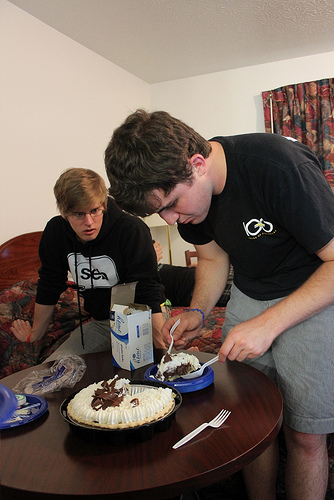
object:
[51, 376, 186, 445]
pie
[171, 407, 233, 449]
fork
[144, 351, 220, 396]
plates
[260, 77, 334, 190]
curtain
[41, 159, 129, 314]
boy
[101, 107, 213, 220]
hair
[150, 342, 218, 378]
pie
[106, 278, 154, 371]
box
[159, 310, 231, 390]
forks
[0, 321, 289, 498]
table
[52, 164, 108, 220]
hair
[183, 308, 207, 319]
bracelet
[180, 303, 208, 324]
wrist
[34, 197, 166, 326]
hoodie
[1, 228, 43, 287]
cot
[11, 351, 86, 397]
bag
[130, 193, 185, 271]
lamp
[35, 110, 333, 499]
boys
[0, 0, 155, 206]
wall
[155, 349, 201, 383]
chocolate pie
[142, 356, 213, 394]
blue plate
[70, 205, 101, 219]
glasses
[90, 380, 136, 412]
curls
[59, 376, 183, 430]
pie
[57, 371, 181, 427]
pie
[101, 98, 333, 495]
man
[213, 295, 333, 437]
shorts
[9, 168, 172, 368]
boy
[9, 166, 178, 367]
person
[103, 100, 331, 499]
boy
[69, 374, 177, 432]
cake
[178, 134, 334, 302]
shirt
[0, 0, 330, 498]
room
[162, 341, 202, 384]
pie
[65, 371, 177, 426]
whipped cream